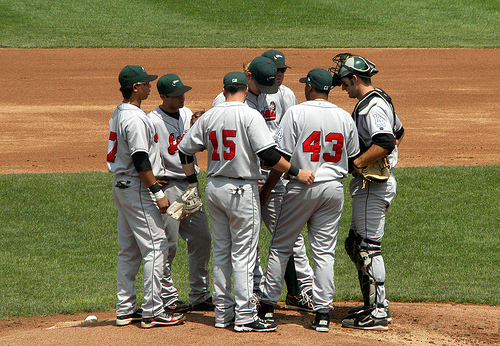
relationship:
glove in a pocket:
[114, 180, 135, 189] [116, 178, 134, 200]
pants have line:
[114, 175, 168, 320] [137, 177, 159, 320]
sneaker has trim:
[141, 309, 188, 327] [173, 316, 178, 327]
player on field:
[331, 54, 405, 330] [3, 2, 500, 344]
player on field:
[258, 68, 358, 331] [3, 2, 500, 344]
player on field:
[179, 73, 314, 331] [3, 2, 500, 344]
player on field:
[148, 76, 213, 318] [3, 2, 500, 344]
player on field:
[107, 67, 187, 324] [3, 2, 500, 344]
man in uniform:
[331, 54, 405, 330] [331, 51, 404, 329]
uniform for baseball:
[331, 51, 404, 329] [3, 2, 500, 344]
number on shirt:
[206, 129, 237, 163] [177, 99, 278, 179]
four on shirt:
[304, 129, 322, 161] [277, 99, 362, 182]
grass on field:
[1, 1, 499, 318] [3, 2, 500, 344]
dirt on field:
[3, 47, 499, 344] [3, 2, 500, 344]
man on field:
[213, 55, 314, 311] [3, 2, 500, 344]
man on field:
[331, 54, 405, 330] [3, 2, 500, 344]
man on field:
[258, 68, 358, 331] [3, 2, 500, 344]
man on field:
[179, 73, 314, 331] [3, 2, 500, 344]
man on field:
[107, 67, 187, 324] [3, 2, 500, 344]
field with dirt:
[3, 2, 500, 344] [3, 47, 499, 344]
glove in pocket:
[231, 186, 246, 198] [228, 190, 246, 209]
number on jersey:
[303, 129, 345, 163] [277, 99, 362, 182]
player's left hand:
[351, 158, 391, 192] [353, 153, 368, 181]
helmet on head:
[330, 52, 378, 83] [329, 50, 377, 99]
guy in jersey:
[258, 68, 358, 331] [277, 99, 362, 182]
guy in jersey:
[179, 73, 314, 331] [177, 99, 278, 179]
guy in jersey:
[148, 76, 213, 318] [147, 106, 201, 179]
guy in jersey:
[107, 67, 187, 324] [109, 103, 164, 179]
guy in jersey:
[331, 54, 405, 330] [351, 88, 405, 179]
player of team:
[258, 68, 358, 331] [96, 51, 403, 332]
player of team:
[179, 73, 314, 331] [96, 51, 403, 332]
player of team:
[107, 67, 187, 324] [96, 51, 403, 332]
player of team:
[148, 76, 213, 318] [96, 51, 403, 332]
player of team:
[331, 54, 405, 330] [96, 51, 403, 332]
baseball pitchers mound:
[3, 2, 500, 344] [3, 299, 499, 345]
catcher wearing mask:
[331, 54, 405, 330] [328, 53, 352, 87]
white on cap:
[322, 84, 331, 92] [299, 67, 334, 93]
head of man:
[329, 50, 377, 99] [331, 54, 405, 330]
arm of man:
[251, 109, 299, 189] [179, 73, 314, 331]